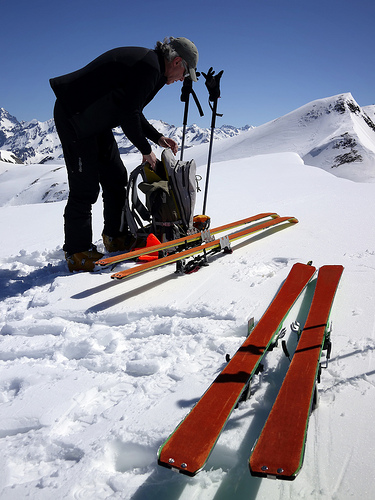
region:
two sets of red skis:
[60, 206, 360, 480]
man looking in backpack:
[53, 36, 214, 278]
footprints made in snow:
[23, 302, 204, 394]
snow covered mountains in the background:
[17, 89, 359, 173]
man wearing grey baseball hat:
[158, 28, 204, 94]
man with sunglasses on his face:
[148, 34, 205, 97]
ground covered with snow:
[249, 178, 302, 201]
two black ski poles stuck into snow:
[156, 61, 232, 222]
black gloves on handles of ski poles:
[176, 64, 226, 105]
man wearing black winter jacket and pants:
[56, 34, 168, 270]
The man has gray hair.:
[153, 32, 202, 88]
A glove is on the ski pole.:
[195, 60, 240, 108]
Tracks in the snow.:
[9, 294, 229, 384]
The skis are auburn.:
[150, 256, 337, 475]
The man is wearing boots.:
[54, 210, 144, 275]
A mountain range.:
[152, 112, 243, 142]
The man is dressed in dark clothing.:
[40, 15, 199, 245]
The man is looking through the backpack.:
[115, 24, 197, 234]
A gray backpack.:
[123, 150, 198, 240]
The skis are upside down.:
[94, 199, 293, 284]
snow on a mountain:
[257, 54, 372, 186]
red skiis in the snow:
[229, 110, 325, 486]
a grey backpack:
[118, 131, 216, 255]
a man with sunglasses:
[37, 8, 213, 285]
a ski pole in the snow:
[200, 55, 234, 256]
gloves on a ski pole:
[204, 58, 236, 152]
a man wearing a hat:
[37, 11, 234, 342]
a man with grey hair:
[22, 2, 215, 251]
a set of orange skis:
[68, 185, 317, 285]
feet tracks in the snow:
[9, 300, 171, 414]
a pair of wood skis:
[92, 210, 297, 279]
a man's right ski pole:
[193, 68, 223, 230]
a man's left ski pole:
[177, 69, 201, 159]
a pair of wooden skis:
[154, 261, 341, 479]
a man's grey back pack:
[124, 148, 200, 240]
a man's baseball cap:
[165, 32, 198, 82]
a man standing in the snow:
[47, 34, 200, 274]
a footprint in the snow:
[0, 437, 83, 490]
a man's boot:
[66, 248, 106, 272]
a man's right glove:
[201, 65, 223, 97]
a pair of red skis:
[145, 254, 348, 488]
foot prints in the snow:
[6, 308, 169, 497]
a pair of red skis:
[94, 208, 301, 290]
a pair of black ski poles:
[175, 61, 224, 228]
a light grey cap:
[163, 28, 203, 85]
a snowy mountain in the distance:
[228, 91, 373, 191]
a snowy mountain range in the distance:
[2, 102, 261, 170]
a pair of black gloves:
[175, 66, 224, 104]